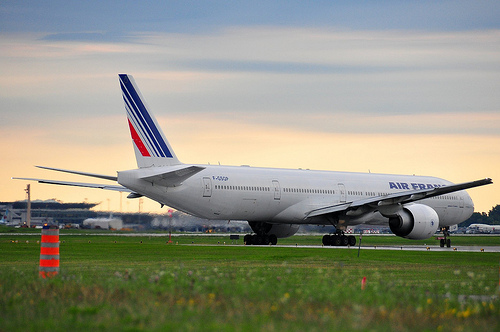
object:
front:
[419, 175, 474, 228]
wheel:
[257, 235, 277, 245]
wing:
[113, 73, 178, 165]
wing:
[310, 175, 493, 220]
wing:
[34, 165, 118, 181]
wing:
[139, 158, 206, 188]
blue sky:
[0, 1, 498, 213]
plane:
[12, 73, 494, 245]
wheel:
[322, 234, 341, 245]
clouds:
[1, 0, 499, 205]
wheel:
[440, 239, 451, 248]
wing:
[28, 177, 138, 194]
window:
[214, 185, 218, 190]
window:
[268, 186, 271, 191]